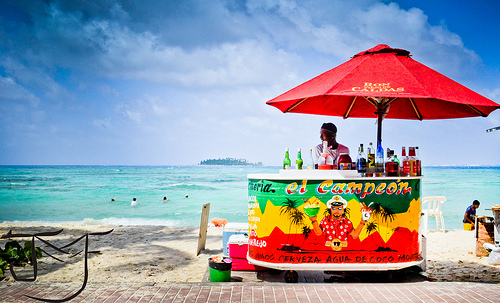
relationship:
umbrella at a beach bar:
[265, 44, 499, 148] [247, 142, 424, 282]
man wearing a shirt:
[462, 200, 479, 230] [462, 206, 475, 223]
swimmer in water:
[111, 197, 116, 202] [1, 165, 500, 226]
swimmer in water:
[130, 197, 138, 206] [1, 165, 500, 226]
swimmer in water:
[163, 195, 168, 203] [1, 165, 500, 226]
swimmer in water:
[185, 194, 189, 199] [1, 165, 500, 226]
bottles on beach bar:
[283, 139, 421, 176] [247, 142, 424, 282]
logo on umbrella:
[339, 82, 411, 97] [265, 44, 499, 148]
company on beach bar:
[286, 179, 413, 199] [247, 142, 424, 282]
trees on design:
[279, 198, 396, 248] [247, 179, 421, 264]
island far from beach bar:
[200, 157, 263, 166] [247, 142, 424, 282]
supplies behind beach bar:
[221, 221, 270, 271] [247, 142, 424, 282]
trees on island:
[198, 158, 263, 165] [200, 157, 263, 166]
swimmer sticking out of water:
[111, 197, 116, 202] [1, 165, 500, 226]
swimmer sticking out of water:
[130, 197, 138, 206] [1, 165, 500, 226]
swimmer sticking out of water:
[163, 195, 168, 203] [1, 165, 500, 226]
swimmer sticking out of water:
[185, 194, 189, 199] [1, 165, 500, 226]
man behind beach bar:
[312, 122, 348, 167] [247, 142, 424, 282]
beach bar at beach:
[247, 142, 424, 282] [1, 164, 500, 303]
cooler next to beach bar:
[229, 234, 268, 271] [247, 142, 424, 282]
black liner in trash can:
[208, 257, 232, 271] [209, 256, 231, 282]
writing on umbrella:
[352, 81, 404, 92] [265, 44, 499, 148]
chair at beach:
[421, 194, 448, 232] [1, 164, 500, 303]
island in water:
[200, 157, 263, 166] [1, 165, 500, 226]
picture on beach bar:
[302, 195, 373, 250] [247, 142, 424, 282]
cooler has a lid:
[229, 234, 268, 271] [228, 234, 248, 245]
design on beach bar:
[247, 179, 421, 264] [247, 142, 424, 282]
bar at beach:
[241, 169, 424, 301] [1, 164, 500, 303]